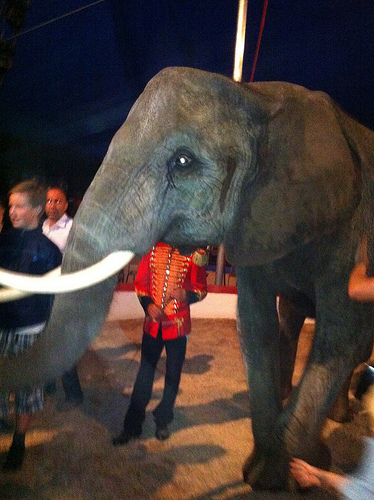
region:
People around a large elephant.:
[1, 66, 372, 498]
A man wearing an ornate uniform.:
[112, 242, 208, 444]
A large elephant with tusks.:
[1, 65, 371, 492]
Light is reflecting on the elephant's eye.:
[173, 151, 191, 167]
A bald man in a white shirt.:
[42, 188, 84, 412]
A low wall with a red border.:
[110, 281, 239, 321]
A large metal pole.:
[212, 0, 248, 283]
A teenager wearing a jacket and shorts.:
[0, 181, 61, 470]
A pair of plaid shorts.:
[0, 334, 46, 415]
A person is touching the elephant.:
[1, 65, 373, 493]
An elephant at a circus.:
[0, 64, 371, 492]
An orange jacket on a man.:
[133, 240, 208, 342]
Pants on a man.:
[122, 329, 187, 429]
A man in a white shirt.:
[39, 185, 73, 254]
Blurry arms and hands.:
[288, 455, 342, 490]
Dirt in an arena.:
[1, 316, 373, 498]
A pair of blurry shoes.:
[111, 416, 171, 446]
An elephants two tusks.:
[1, 249, 134, 302]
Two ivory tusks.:
[0, 249, 135, 301]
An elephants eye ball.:
[176, 153, 192, 167]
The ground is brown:
[74, 441, 163, 498]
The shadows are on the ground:
[78, 411, 239, 497]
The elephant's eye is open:
[162, 146, 231, 195]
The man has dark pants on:
[108, 336, 199, 445]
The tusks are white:
[0, 251, 168, 299]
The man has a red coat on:
[117, 235, 231, 354]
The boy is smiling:
[4, 166, 37, 232]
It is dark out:
[19, 148, 109, 197]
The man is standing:
[72, 276, 228, 424]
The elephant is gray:
[218, 164, 335, 276]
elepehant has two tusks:
[1, 249, 134, 305]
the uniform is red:
[136, 238, 198, 340]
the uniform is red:
[124, 226, 229, 355]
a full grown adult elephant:
[57, 42, 365, 471]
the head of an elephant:
[95, 33, 317, 356]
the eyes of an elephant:
[162, 141, 198, 185]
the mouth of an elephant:
[147, 202, 196, 254]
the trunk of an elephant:
[25, 169, 137, 382]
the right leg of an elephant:
[227, 263, 290, 429]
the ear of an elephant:
[221, 88, 339, 246]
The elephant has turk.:
[5, 252, 161, 288]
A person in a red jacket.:
[138, 260, 206, 331]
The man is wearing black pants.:
[142, 339, 183, 422]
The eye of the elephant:
[158, 139, 237, 192]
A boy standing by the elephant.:
[11, 187, 76, 353]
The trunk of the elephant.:
[7, 224, 106, 391]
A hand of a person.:
[282, 445, 356, 486]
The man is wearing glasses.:
[46, 196, 63, 205]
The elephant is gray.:
[124, 106, 344, 247]